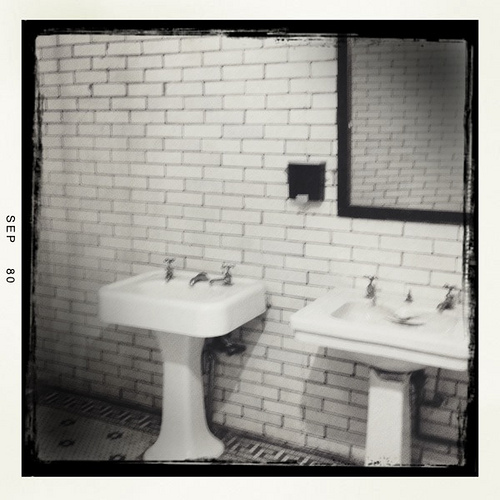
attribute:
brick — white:
[85, 74, 260, 224]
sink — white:
[94, 257, 269, 464]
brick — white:
[36, 34, 454, 464]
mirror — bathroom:
[335, 37, 480, 224]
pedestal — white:
[141, 331, 226, 466]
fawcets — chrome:
[161, 260, 236, 289]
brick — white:
[176, 126, 232, 140]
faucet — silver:
[188, 270, 208, 296]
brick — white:
[251, 382, 329, 425]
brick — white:
[32, 36, 489, 455]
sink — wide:
[299, 269, 485, 379]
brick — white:
[241, 107, 288, 121]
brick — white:
[53, 52, 93, 76]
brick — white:
[194, 140, 254, 157]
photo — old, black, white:
[35, 34, 466, 466]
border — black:
[26, 460, 479, 477]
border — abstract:
[30, 372, 381, 499]